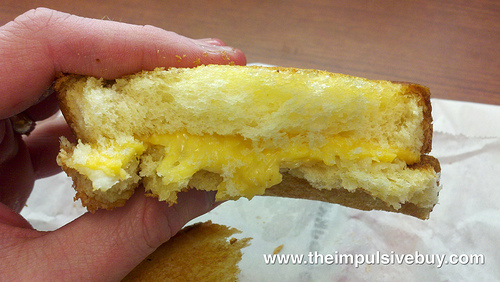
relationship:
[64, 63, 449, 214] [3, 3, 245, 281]
sandwich in hand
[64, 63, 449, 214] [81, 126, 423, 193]
sandwich with melted cheese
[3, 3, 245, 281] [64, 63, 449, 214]
hand holding sandwich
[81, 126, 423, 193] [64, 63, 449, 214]
melted cheese on sandwich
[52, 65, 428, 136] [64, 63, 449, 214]
bread top of sandwich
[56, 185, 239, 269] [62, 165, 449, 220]
thumb holding lower bread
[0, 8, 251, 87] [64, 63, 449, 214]
index finger holding sandwich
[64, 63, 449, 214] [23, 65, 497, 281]
sandwich over white surface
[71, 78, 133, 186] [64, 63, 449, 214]
piece of sandwich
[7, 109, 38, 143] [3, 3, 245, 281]
ring on hand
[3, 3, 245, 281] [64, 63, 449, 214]
hand with sandwich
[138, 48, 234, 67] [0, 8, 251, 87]
crumbs on index finger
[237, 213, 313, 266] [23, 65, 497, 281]
crumbs on white surface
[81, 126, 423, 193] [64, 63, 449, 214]
melted cheese oozing sandwich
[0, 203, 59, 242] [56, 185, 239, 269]
folds on thumb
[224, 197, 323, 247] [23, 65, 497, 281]
oil stains on white surface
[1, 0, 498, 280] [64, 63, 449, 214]
indoor kitchen scene with sandwich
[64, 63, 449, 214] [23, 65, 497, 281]
sandwich with white surface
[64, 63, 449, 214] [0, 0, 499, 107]
sandwich over table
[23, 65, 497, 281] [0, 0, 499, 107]
white surface on table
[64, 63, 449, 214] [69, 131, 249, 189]
sandwich with scrambled egg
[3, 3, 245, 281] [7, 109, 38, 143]
hand has ring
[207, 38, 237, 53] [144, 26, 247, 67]
nails on fingers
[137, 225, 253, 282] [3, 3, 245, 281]
bread below hand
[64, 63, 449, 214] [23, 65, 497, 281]
sandwich above white surface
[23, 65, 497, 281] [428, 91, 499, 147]
white surface folded edge